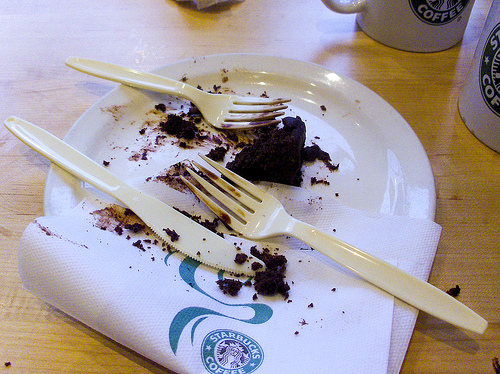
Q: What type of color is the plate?
A: White.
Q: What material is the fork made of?
A: Plastic.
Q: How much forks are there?
A: 2.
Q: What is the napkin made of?
A: Paper.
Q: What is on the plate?
A: Eating utensils.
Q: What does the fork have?
A: It has tines.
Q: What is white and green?
A: The napkin.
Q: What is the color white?
A: The coffee mug.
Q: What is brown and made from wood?
A: The table.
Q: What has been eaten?
A: The cake.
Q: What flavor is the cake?
A: The cake is chocolate.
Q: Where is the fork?
A: On the plate.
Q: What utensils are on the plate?
A: Fork and knife.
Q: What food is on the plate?
A: Chocolate cake.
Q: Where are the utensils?
A: Plate.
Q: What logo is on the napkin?
A: Starbucks.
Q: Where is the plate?
A: On table.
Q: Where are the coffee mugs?
A: Next to the plate.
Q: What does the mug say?
A: Starbucks.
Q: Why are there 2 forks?
A: Sharing.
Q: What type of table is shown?
A: Wood.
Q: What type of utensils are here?
A: Plastic.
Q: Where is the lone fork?
A: On plate.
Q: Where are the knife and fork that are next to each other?
A: On napkin.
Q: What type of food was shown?
A: Cake.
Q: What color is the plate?
A: White.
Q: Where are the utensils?
A: On Plate.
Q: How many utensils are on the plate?
A: 3.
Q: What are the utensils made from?
A: Plastic.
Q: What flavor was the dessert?
A: Chocolate.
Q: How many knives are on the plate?
A: 1.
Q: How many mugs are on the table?
A: 2.